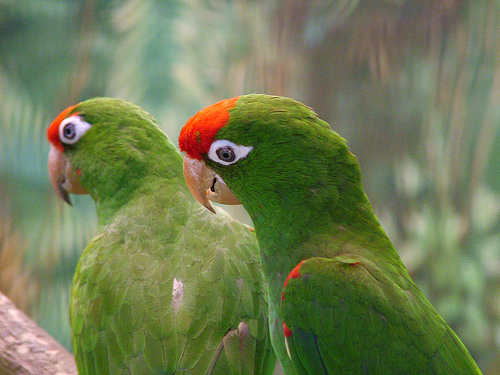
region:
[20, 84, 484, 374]
two birds sitting together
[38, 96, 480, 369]
two green and red parrots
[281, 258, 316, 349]
red spot on top of wing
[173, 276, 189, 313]
white spot on bird's back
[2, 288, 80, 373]
part of branch birds are sitting on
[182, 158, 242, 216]
yellow beak of parrot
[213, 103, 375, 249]
dark green feathers on head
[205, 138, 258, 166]
white area around eye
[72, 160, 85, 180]
Red spot by beak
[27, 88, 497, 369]
two red and green birds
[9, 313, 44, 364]
part of a branch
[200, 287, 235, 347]
part of a feather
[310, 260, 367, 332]
edge of a wing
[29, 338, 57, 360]
part of a wood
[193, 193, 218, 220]
tip of a beak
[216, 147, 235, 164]
A parrot's left eye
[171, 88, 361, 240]
A parrot's green head with a spot of red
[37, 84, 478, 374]
a pair of green parrots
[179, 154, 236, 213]
A parrot's beak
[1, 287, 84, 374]
A part of a wood log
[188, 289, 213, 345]
a single green feather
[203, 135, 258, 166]
White feathers around a parrot's eye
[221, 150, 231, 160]
A parrot's pupil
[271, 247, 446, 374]
The wing of a parrot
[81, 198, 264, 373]
A parrots back side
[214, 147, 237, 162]
The eyeball of a green and red parrot.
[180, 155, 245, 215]
The beak of a green and red parrot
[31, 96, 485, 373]
Two parrots resting on a branch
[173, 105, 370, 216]
Full head of a green and red parrot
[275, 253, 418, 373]
The wing of a green and red parrot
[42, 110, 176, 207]
Head of a green and red parrot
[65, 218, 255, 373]
The backside of a parrot resting on a branch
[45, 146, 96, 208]
A closed beak of a green and red parrot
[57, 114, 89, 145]
White feathers around the eye of a parrot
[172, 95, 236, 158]
Red plume on the head of a parrot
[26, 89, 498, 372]
There are two parrots.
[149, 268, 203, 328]
Grey on the chest.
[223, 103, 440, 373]
Parrot is dark green.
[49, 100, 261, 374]
Parrot is light green.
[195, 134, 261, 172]
Area around the eyes is white.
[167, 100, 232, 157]
Red on the forehead.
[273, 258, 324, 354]
Red on the wing.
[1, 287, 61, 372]
Tree limb next to the birds.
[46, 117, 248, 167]
The eyes are grey.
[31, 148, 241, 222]
The beaks are pale orange.